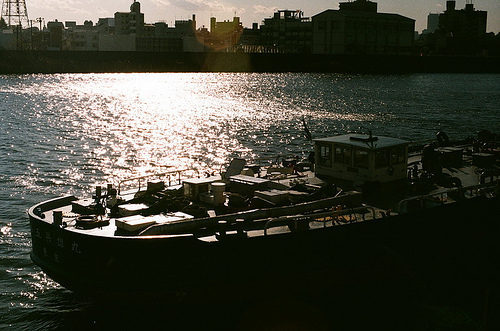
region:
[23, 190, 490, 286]
BIG DARK BARGE ON WATER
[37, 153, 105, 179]
water is dark and rippled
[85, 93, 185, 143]
sun reflecting off water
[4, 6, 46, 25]
cell tower in distance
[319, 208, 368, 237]
yellow object on deck of barge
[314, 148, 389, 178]
captains room on boat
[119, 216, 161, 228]
square hatch on boat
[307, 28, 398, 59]
big tan building in distance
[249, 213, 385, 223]
metal railing on boat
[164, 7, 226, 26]
white wispy clouds in sky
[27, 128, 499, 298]
A long flat boat with little room on top.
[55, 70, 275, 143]
White water top with sun shining down on it.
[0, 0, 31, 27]
Large metal power tower.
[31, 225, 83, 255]
Chinese symbols on the front of a boat.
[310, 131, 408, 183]
A small room on top of the boat.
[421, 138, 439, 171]
Barely visible person behind the little room on the boat.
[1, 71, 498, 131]
All the water above the boat.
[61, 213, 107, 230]
Large wound up rope at the front of the boat.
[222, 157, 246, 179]
An open hatch across the boat in the middle.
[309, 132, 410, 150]
A dark roof of a little room.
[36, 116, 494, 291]
A boat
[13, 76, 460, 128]
The river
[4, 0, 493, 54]
Multiple buildings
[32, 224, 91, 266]
Asian writing on the front of the ship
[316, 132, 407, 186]
The cabin on the ship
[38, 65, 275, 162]
Reflection from the sun on the water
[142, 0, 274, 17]
The skyline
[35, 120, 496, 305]
A large ship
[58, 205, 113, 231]
Rope on the front of the boat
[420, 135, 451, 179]
A man sitting on the boat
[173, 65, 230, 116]
part of a light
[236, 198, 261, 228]
part of a metal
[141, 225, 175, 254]
edge of a ship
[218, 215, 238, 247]
part of a ,etal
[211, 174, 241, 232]
part of a metal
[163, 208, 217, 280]
part of a ship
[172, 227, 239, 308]
edge of a ship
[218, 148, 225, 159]
part of a water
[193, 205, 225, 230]
part of a etal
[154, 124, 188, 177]
part fo a water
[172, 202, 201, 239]
part of a metal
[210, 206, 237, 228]
edge of a ship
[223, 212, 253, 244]
edge of a ship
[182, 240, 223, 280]
edge of a ship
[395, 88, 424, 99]
part fo a wave